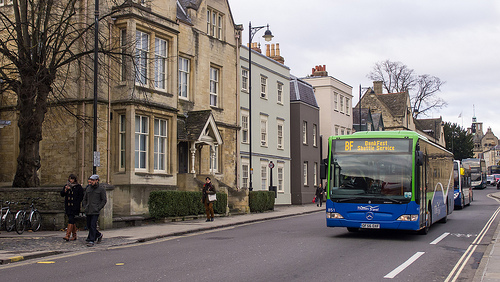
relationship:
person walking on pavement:
[201, 177, 218, 222] [2, 200, 322, 252]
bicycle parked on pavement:
[27, 201, 51, 223] [4, 203, 154, 263]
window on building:
[259, 72, 267, 102] [239, 43, 292, 206]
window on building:
[240, 113, 251, 147] [239, 43, 292, 206]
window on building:
[231, 156, 250, 181] [239, 43, 292, 206]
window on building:
[254, 162, 271, 196] [239, 43, 292, 206]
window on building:
[275, 160, 281, 190] [239, 43, 292, 206]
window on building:
[258, 113, 273, 154] [235, 29, 295, 211]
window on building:
[277, 87, 284, 104] [235, 29, 295, 211]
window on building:
[278, 118, 280, 146] [235, 29, 295, 211]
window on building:
[274, 160, 289, 186] [235, 29, 295, 211]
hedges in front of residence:
[145, 188, 229, 219] [6, 2, 246, 222]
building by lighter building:
[292, 75, 324, 202] [239, 45, 298, 194]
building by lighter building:
[292, 75, 324, 202] [307, 71, 359, 145]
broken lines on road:
[383, 231, 450, 278] [1, 186, 498, 281]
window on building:
[256, 70, 268, 100] [236, 39, 296, 206]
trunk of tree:
[10, 90, 57, 157] [15, 1, 125, 256]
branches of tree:
[7, 13, 145, 81] [2, 1, 155, 186]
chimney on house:
[355, 71, 392, 95] [335, 77, 437, 137]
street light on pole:
[249, 22, 276, 46] [244, 75, 256, 165]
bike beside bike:
[16, 203, 50, 230] [1, 203, 26, 225]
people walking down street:
[57, 172, 107, 248] [112, 245, 474, 278]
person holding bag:
[171, 174, 259, 227] [206, 193, 216, 203]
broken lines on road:
[383, 250, 427, 277] [304, 226, 402, 278]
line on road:
[432, 230, 452, 248] [304, 226, 402, 278]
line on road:
[454, 251, 464, 264] [304, 226, 402, 278]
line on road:
[469, 245, 476, 258] [304, 226, 402, 278]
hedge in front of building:
[250, 188, 276, 213] [7, 2, 235, 221]